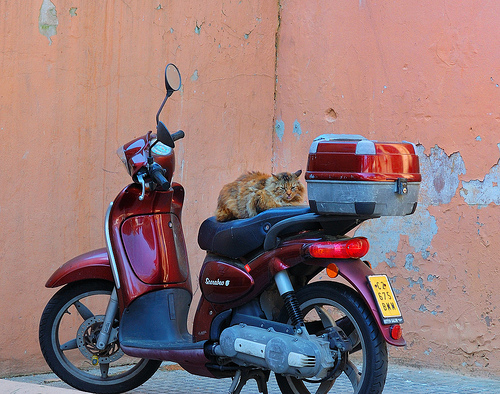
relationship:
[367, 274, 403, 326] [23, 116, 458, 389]
plate on scooter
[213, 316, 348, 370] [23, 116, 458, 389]
drive line scooter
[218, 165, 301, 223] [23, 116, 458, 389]
cat on scooter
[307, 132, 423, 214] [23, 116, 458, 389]
luggage for scooter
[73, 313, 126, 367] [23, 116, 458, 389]
disc brakes scooter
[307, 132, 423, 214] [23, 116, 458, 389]
door on scooter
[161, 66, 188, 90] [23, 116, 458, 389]
mirror on scooter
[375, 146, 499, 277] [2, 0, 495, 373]
paint off wall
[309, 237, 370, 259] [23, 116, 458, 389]
light on scooter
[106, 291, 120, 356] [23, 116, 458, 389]
shock on scooter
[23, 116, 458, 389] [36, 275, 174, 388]
motorcycle front tire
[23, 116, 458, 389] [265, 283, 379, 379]
motorcycle rear tire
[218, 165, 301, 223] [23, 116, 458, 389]
cat on motorcycle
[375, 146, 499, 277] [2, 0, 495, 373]
paint on wall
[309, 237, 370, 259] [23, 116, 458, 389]
light on motorcycle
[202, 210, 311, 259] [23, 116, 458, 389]
seat on moped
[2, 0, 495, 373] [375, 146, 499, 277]
building with paint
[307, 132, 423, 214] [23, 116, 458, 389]
case on moped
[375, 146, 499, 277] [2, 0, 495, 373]
peeling on wall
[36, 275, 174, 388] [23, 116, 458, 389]
front of scooter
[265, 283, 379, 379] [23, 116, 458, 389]
back wheel scooter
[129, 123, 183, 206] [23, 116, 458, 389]
bars of scooter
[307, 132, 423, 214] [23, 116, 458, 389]
storage on scooter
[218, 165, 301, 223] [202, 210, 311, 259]
cat on seat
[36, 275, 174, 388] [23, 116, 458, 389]
wheel on scooter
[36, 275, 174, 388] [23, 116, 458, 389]
wheel of scooter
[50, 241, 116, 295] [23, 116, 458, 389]
fender on scooter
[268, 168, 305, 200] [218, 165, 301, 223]
head of cat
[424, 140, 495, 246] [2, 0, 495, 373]
chips on wall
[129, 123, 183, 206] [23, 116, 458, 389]
bars on scooter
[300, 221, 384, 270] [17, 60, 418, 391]
light of scooter